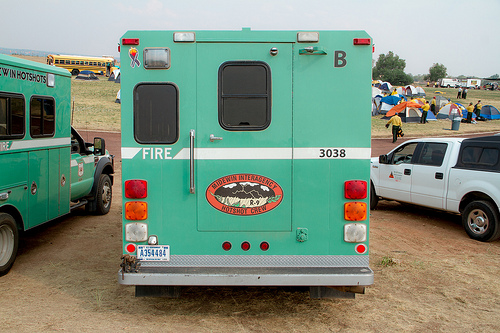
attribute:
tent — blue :
[468, 97, 499, 122]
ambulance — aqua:
[116, 27, 373, 296]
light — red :
[335, 171, 376, 245]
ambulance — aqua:
[0, 55, 114, 277]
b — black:
[333, 50, 347, 69]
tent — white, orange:
[434, 100, 464, 120]